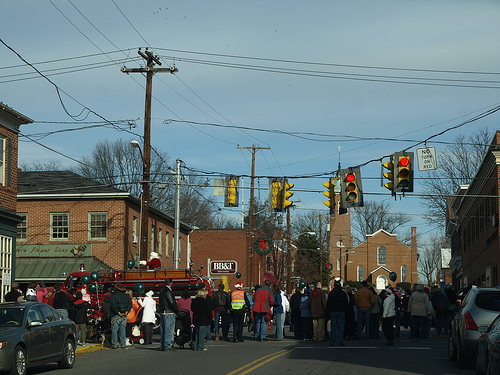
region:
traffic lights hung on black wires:
[184, 106, 496, 213]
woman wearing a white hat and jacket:
[136, 288, 159, 325]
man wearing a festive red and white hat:
[229, 278, 248, 290]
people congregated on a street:
[6, 273, 458, 343]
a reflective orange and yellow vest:
[228, 286, 248, 313]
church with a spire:
[328, 141, 421, 280]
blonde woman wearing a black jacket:
[190, 287, 214, 328]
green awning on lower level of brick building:
[9, 198, 189, 283]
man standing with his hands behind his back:
[107, 280, 130, 348]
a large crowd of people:
[93, 265, 440, 347]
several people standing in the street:
[108, 270, 439, 362]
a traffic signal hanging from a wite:
[385, 140, 415, 201]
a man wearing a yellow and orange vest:
[222, 281, 252, 345]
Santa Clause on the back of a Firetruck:
[75, 250, 201, 285]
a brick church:
[328, 145, 427, 294]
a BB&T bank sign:
[206, 255, 237, 280]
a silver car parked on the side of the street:
[444, 278, 494, 366]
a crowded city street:
[80, 182, 450, 365]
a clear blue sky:
[196, 1, 488, 49]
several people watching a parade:
[10, 278, 465, 353]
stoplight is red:
[392, 150, 414, 192]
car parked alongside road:
[0, 297, 83, 372]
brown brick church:
[327, 189, 416, 281]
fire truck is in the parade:
[62, 249, 210, 296]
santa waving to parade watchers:
[136, 249, 162, 272]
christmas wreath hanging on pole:
[250, 234, 272, 256]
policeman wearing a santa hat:
[230, 279, 251, 344]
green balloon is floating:
[386, 270, 398, 282]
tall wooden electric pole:
[120, 45, 180, 257]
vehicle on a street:
[0, 293, 84, 372]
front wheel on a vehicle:
[6, 340, 32, 373]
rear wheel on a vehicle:
[55, 332, 80, 372]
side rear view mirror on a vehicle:
[24, 315, 45, 332]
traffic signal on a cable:
[335, 160, 370, 215]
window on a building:
[83, 207, 111, 245]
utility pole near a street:
[113, 40, 189, 278]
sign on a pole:
[206, 256, 241, 279]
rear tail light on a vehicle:
[458, 307, 483, 336]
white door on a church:
[374, 271, 391, 294]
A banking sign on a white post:
[206, 257, 238, 292]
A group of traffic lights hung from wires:
[223, 149, 416, 214]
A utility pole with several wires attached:
[118, 45, 180, 271]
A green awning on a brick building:
[13, 255, 115, 284]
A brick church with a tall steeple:
[323, 144, 419, 298]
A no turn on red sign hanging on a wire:
[415, 137, 437, 172]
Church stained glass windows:
[353, 243, 409, 285]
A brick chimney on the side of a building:
[408, 224, 420, 286]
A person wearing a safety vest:
[227, 281, 249, 345]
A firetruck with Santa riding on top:
[44, 251, 216, 336]